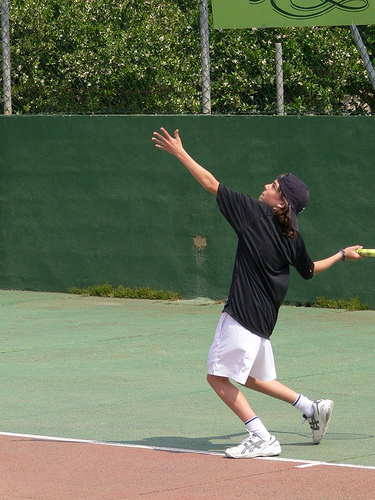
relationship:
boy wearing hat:
[151, 127, 373, 457] [275, 168, 312, 232]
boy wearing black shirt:
[151, 127, 373, 457] [211, 180, 314, 340]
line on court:
[14, 430, 373, 476] [1, 287, 369, 499]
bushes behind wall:
[8, 4, 370, 114] [4, 113, 374, 298]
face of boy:
[258, 175, 277, 203] [151, 127, 363, 460]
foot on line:
[214, 413, 292, 486] [73, 431, 183, 467]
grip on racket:
[357, 247, 375, 258] [353, 243, 374, 260]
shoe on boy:
[303, 384, 332, 437] [151, 127, 373, 457]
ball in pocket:
[224, 335, 247, 354] [221, 321, 247, 358]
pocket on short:
[221, 321, 247, 358] [207, 312, 274, 384]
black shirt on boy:
[211, 180, 319, 341] [151, 127, 373, 457]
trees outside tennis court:
[10, 4, 361, 116] [2, 287, 370, 498]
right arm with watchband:
[305, 244, 364, 282] [335, 245, 349, 265]